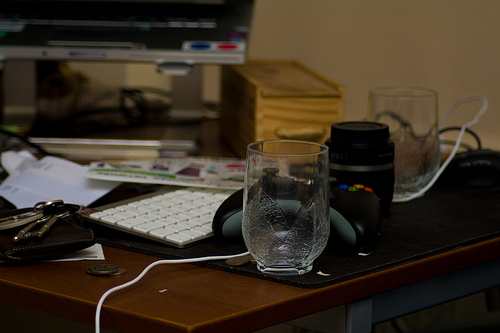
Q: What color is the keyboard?
A: White.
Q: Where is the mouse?
A: Behind the glass.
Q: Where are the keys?
A: On the left side.